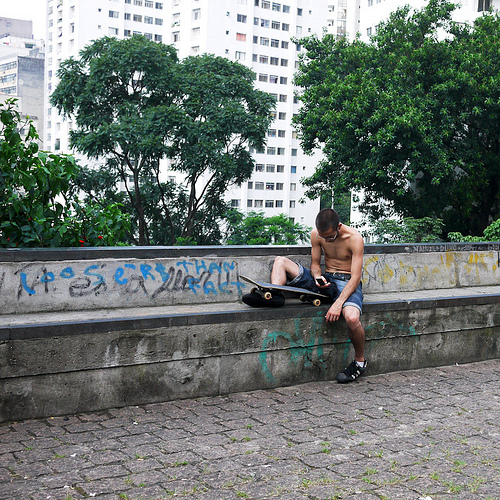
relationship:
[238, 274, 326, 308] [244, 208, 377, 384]
skateboard near man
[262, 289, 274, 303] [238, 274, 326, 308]
wheel of skateboard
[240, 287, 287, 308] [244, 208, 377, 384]
shoe of man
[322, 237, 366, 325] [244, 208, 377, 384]
arm of man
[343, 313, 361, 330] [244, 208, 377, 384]
knee of man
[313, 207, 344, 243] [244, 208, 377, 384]
head of man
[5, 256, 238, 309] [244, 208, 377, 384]
grafitti near man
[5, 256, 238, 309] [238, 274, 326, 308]
grafitti near skateboard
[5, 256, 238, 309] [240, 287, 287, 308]
grafitti near shoe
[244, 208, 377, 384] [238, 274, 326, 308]
man with skateboard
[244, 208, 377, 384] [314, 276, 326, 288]
man checking phone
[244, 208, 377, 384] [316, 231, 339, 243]
man wearing glasses